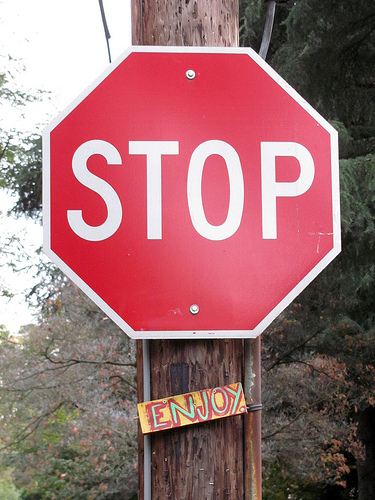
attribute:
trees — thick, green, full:
[4, 6, 375, 494]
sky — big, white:
[3, 12, 117, 323]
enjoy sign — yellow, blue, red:
[133, 374, 254, 439]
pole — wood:
[129, 0, 240, 47]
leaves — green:
[281, 7, 355, 90]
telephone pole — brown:
[129, 0, 264, 499]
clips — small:
[242, 398, 266, 417]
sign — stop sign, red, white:
[40, 43, 344, 338]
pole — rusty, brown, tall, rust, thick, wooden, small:
[129, 2, 270, 498]